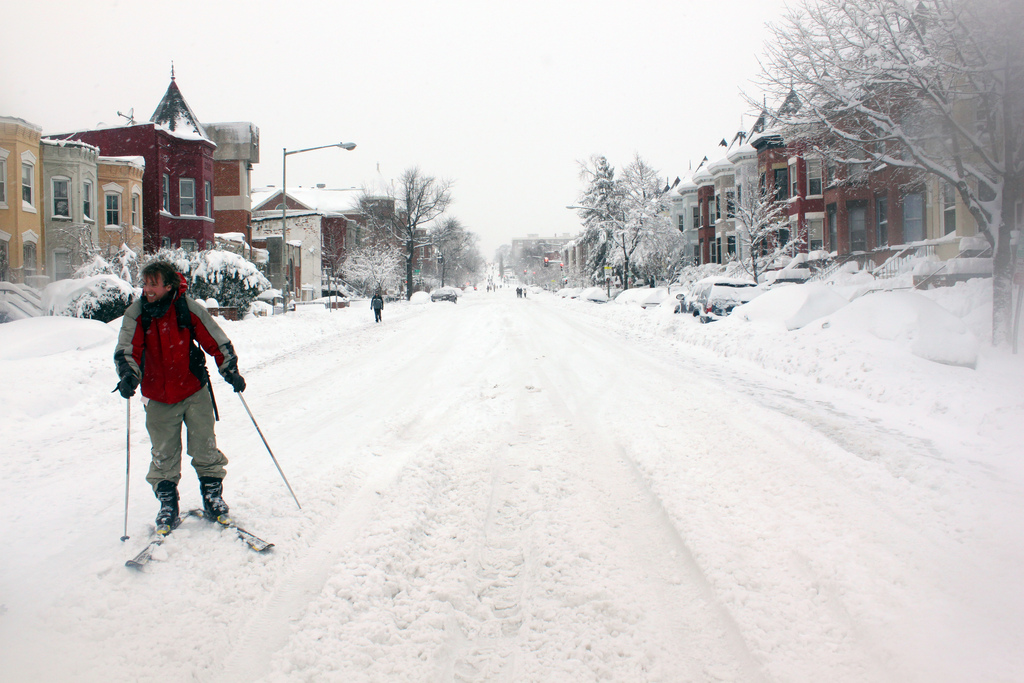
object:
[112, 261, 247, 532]
man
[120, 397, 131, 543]
ski pole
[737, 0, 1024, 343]
tree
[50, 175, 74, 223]
window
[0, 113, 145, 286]
building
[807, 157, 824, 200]
window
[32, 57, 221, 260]
building